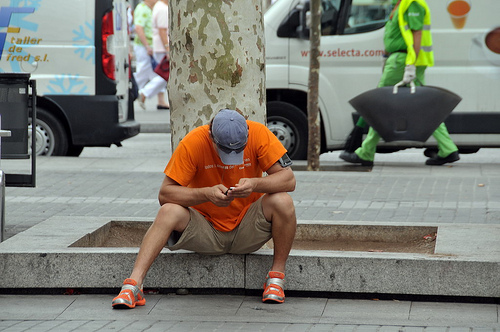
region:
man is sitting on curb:
[108, 108, 298, 309]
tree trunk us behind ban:
[161, 2, 286, 157]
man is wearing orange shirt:
[163, 125, 288, 220]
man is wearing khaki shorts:
[173, 195, 277, 256]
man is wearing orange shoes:
[109, 270, 294, 316]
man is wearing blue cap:
[207, 114, 252, 169]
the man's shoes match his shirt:
[118, 125, 285, 309]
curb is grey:
[6, 253, 498, 291]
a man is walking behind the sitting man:
[338, 3, 462, 170]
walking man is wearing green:
[342, 3, 461, 173]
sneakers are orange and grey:
[106, 280, 163, 324]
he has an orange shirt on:
[174, 123, 307, 215]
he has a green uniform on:
[373, 27, 453, 197]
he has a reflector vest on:
[374, 6, 491, 111]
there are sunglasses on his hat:
[210, 133, 281, 195]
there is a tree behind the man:
[160, 8, 343, 233]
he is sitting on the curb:
[115, 139, 301, 312]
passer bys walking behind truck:
[128, 3, 215, 152]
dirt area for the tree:
[333, 228, 447, 294]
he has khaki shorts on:
[169, 203, 379, 319]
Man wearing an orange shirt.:
[87, 101, 324, 311]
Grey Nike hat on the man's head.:
[198, 85, 265, 174]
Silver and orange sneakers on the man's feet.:
[76, 262, 312, 317]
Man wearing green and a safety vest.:
[314, 0, 484, 179]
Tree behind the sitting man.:
[134, 0, 311, 255]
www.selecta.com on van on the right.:
[296, 41, 401, 64]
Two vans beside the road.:
[3, 0, 499, 159]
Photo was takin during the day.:
[0, 0, 492, 323]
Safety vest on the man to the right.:
[353, 2, 448, 75]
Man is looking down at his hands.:
[198, 103, 283, 242]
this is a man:
[103, 113, 308, 313]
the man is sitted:
[106, 110, 301, 319]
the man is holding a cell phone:
[225, 181, 240, 199]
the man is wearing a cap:
[219, 115, 241, 160]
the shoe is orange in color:
[264, 273, 284, 295]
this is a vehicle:
[43, 5, 120, 132]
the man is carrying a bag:
[360, 85, 447, 137]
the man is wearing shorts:
[184, 219, 262, 245]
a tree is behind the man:
[175, 3, 255, 114]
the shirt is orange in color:
[253, 140, 270, 162]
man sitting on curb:
[88, 88, 315, 323]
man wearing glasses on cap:
[192, 90, 272, 187]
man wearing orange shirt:
[148, 112, 359, 273]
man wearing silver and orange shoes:
[100, 269, 150, 330]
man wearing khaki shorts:
[159, 172, 346, 279]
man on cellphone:
[221, 163, 275, 222]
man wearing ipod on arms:
[250, 130, 315, 207]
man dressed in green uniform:
[346, 0, 498, 202]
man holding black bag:
[346, 47, 497, 177]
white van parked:
[227, 2, 498, 166]